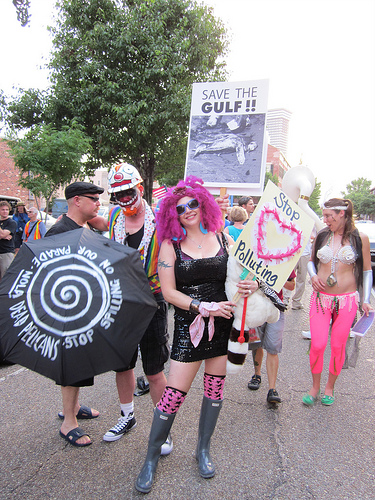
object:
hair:
[156, 177, 223, 241]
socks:
[156, 371, 227, 418]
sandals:
[55, 404, 102, 447]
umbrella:
[0, 225, 160, 383]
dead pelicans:
[7, 301, 61, 363]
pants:
[307, 291, 358, 375]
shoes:
[302, 389, 336, 409]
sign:
[179, 77, 271, 197]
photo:
[186, 113, 264, 184]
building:
[264, 103, 295, 158]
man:
[98, 157, 177, 456]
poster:
[226, 180, 318, 303]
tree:
[10, 0, 84, 219]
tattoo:
[154, 257, 172, 271]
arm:
[156, 237, 209, 319]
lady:
[132, 175, 259, 496]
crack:
[264, 408, 293, 500]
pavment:
[210, 400, 374, 496]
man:
[41, 180, 105, 449]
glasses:
[82, 193, 103, 203]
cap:
[62, 182, 105, 200]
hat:
[107, 160, 143, 194]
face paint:
[112, 188, 143, 217]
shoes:
[102, 408, 175, 456]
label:
[158, 413, 168, 422]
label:
[210, 401, 222, 409]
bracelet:
[187, 297, 201, 318]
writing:
[10, 246, 124, 362]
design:
[25, 252, 111, 338]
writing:
[231, 237, 279, 290]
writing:
[271, 188, 300, 224]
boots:
[134, 398, 221, 494]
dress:
[165, 238, 231, 361]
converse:
[103, 408, 177, 457]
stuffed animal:
[225, 238, 281, 368]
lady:
[300, 196, 374, 412]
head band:
[321, 202, 350, 214]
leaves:
[110, 98, 126, 121]